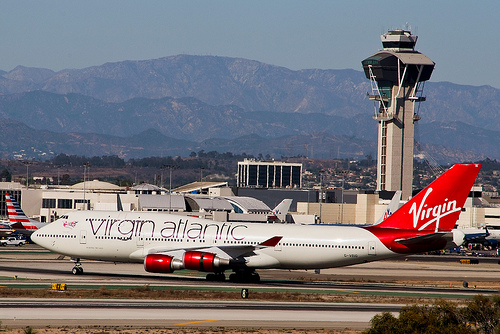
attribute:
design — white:
[1, 192, 36, 231]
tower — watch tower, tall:
[360, 18, 437, 223]